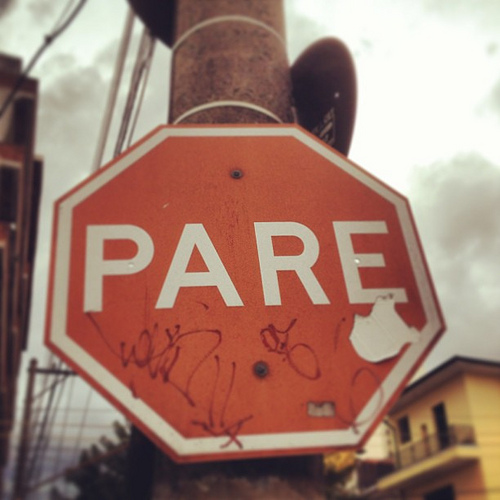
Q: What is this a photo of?
A: A sign.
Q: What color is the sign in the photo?
A: Red.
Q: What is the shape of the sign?
A: Octagon.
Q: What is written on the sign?
A: PARE.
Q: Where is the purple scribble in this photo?
A: Under the words PARE on the red sign.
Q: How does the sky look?
A: Cloudy.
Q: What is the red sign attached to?
A: A rusty brown pole.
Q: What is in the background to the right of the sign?
A: A house.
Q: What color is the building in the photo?
A: Yellow.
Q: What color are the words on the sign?
A: White.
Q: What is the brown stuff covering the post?
A: Rust.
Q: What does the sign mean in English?
A: Stop.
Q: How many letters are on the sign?
A: 4.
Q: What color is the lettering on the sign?
A: White.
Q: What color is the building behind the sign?
A: Yellow.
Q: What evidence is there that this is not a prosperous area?
A: Disrepair.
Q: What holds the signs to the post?
A: Straps.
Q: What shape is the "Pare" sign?
A: Octagon.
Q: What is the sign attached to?
A: A pole.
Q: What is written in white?
A: Pare.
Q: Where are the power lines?
A: Above the sign.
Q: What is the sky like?
A: Cloudy.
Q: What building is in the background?
A: A house.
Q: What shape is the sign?
A: An octagon.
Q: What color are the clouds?
A: Grey.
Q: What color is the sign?
A: Red.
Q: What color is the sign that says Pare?
A: Red.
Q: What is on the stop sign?
A: Black graffiti.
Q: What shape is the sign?
A: Octagon.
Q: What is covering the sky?
A: Clouds.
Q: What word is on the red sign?
A: PARE.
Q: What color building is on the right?
A: Yellow.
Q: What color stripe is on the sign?
A: White.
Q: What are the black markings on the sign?
A: Graffiti.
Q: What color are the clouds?
A: Grey.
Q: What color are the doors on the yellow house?
A: Black.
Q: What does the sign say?
A: PARE.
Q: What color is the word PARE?
A: White.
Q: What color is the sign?
A: Red.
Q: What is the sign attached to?
A: Pole.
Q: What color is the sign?
A: Red.